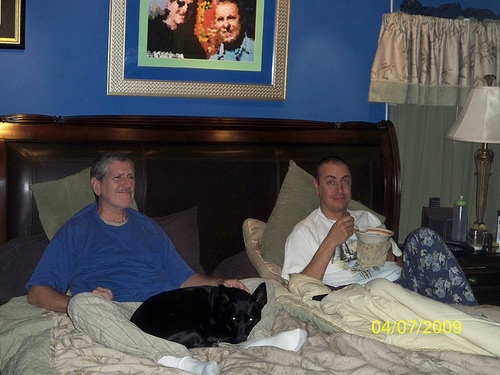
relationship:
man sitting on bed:
[33, 153, 309, 374] [2, 111, 500, 370]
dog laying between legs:
[130, 273, 271, 349] [61, 284, 307, 372]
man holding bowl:
[282, 158, 484, 309] [344, 218, 397, 243]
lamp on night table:
[448, 73, 500, 252] [385, 228, 500, 310]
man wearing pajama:
[282, 158, 484, 309] [394, 228, 476, 303]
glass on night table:
[466, 230, 484, 257] [385, 228, 500, 310]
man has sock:
[33, 153, 309, 374] [156, 354, 219, 374]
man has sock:
[33, 153, 309, 374] [252, 323, 308, 355]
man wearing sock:
[33, 153, 309, 374] [156, 354, 219, 374]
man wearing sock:
[33, 153, 309, 374] [252, 323, 308, 355]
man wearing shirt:
[282, 158, 484, 309] [282, 208, 412, 286]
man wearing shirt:
[33, 153, 309, 374] [27, 202, 206, 310]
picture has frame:
[103, 1, 287, 99] [107, 0, 290, 94]